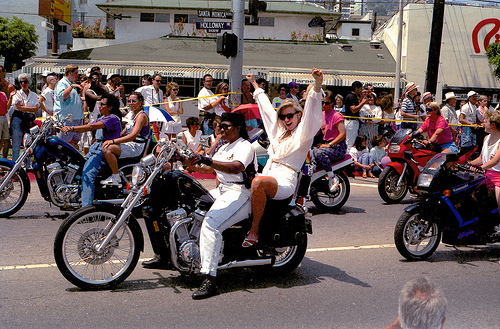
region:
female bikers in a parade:
[2, 41, 497, 302]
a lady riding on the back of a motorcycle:
[240, 70, 326, 261]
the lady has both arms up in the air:
[241, 70, 322, 256]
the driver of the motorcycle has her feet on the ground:
[140, 105, 253, 305]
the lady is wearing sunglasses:
[213, 113, 244, 143]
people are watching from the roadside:
[2, 58, 497, 158]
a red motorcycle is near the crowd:
[376, 83, 497, 199]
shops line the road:
[10, 5, 498, 141]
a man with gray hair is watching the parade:
[390, 270, 445, 326]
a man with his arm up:
[49, 60, 88, 149]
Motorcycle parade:
[78, 86, 432, 321]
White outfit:
[236, 48, 364, 255]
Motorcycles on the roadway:
[37, 108, 391, 291]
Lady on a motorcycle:
[406, 101, 492, 196]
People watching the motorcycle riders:
[84, 67, 243, 147]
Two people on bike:
[74, 83, 163, 142]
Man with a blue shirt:
[46, 54, 129, 151]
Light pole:
[218, 26, 252, 114]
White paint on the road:
[289, 242, 338, 264]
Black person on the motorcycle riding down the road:
[176, 104, 301, 289]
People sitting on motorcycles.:
[0, 68, 499, 298]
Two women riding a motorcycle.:
[54, 69, 324, 299]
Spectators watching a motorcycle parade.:
[2, 60, 498, 180]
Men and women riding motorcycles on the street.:
[0, 88, 498, 326]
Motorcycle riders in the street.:
[0, 67, 498, 323]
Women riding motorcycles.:
[0, 79, 498, 313]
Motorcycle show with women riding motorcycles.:
[2, 66, 499, 324]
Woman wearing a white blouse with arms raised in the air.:
[245, 67, 325, 248]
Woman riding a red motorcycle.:
[377, 100, 479, 204]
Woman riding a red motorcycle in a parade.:
[377, 100, 459, 205]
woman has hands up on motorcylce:
[234, 63, 326, 257]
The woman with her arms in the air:
[243, 69, 327, 259]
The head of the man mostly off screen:
[388, 265, 448, 327]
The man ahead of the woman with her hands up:
[187, 113, 257, 300]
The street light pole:
[212, 1, 251, 111]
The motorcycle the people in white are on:
[47, 145, 313, 293]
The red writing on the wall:
[466, 11, 498, 56]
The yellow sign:
[34, 0, 78, 30]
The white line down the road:
[1, 231, 448, 277]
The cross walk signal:
[214, 31, 238, 58]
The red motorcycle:
[375, 128, 458, 204]